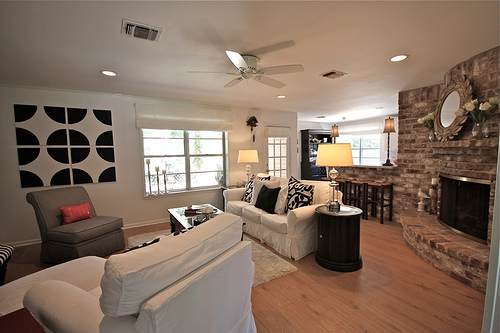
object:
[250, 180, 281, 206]
pillows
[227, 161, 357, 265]
sofa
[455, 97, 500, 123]
white roses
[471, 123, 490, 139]
vase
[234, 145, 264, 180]
silver lamp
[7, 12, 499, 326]
room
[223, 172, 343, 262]
couch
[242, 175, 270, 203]
pillows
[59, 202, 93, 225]
pillow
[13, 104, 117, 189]
art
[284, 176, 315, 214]
pillow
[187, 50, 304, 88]
ceiling fan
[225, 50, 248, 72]
blade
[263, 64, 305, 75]
blade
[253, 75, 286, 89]
blade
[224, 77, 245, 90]
blade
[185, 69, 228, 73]
blade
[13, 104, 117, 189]
picture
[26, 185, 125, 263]
chair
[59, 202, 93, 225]
red pillow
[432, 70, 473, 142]
framed mirror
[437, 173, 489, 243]
fireplace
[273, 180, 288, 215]
pillows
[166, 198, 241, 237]
table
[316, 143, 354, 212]
lamp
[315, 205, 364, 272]
end table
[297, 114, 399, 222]
wall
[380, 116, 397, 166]
table lamp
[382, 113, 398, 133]
shade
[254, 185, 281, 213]
pillow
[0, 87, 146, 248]
wall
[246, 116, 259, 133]
clock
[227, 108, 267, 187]
wall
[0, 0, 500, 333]
living room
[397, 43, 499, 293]
wall